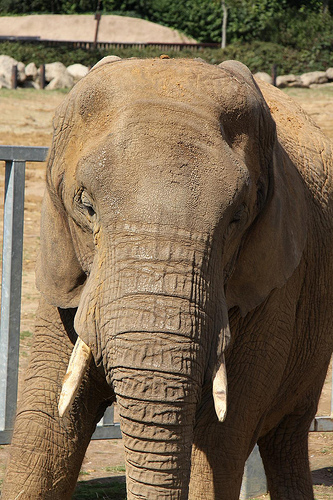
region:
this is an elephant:
[20, 38, 322, 496]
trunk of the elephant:
[80, 203, 240, 498]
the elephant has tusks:
[50, 273, 249, 449]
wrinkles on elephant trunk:
[68, 215, 240, 498]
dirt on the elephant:
[0, 31, 332, 272]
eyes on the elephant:
[71, 169, 261, 257]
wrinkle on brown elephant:
[100, 291, 209, 320]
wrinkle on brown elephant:
[108, 329, 200, 343]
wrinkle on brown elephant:
[105, 364, 196, 382]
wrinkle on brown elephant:
[115, 392, 194, 408]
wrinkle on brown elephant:
[119, 413, 192, 433]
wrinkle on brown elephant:
[118, 427, 182, 445]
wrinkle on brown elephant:
[123, 444, 179, 457]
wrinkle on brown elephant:
[124, 460, 180, 472]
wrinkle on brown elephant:
[127, 474, 182, 493]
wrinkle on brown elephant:
[14, 407, 57, 421]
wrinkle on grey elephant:
[110, 225, 216, 251]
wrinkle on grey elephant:
[104, 328, 210, 356]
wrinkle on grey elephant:
[109, 362, 199, 387]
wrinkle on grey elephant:
[115, 390, 196, 407]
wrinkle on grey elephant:
[118, 410, 192, 430]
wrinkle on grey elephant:
[120, 428, 180, 443]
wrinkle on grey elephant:
[128, 461, 182, 476]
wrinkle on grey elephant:
[14, 407, 53, 420]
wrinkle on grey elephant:
[9, 441, 46, 458]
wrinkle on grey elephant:
[126, 486, 144, 496]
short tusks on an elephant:
[56, 333, 222, 415]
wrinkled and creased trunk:
[92, 233, 215, 497]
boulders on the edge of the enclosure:
[0, 53, 332, 96]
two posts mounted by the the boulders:
[11, 62, 46, 87]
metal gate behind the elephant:
[0, 139, 118, 448]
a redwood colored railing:
[21, 37, 218, 53]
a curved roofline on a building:
[3, 11, 199, 43]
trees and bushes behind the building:
[129, 2, 332, 68]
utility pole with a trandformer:
[93, 4, 103, 46]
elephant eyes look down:
[69, 175, 251, 235]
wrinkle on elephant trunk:
[129, 489, 147, 498]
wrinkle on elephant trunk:
[128, 473, 182, 492]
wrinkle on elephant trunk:
[126, 457, 188, 473]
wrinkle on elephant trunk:
[146, 457, 171, 465]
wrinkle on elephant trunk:
[124, 444, 188, 456]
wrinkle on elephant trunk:
[119, 427, 181, 444]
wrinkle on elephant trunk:
[119, 413, 187, 429]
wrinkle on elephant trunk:
[152, 409, 183, 418]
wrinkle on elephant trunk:
[116, 391, 183, 406]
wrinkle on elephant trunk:
[108, 363, 193, 382]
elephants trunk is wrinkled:
[85, 192, 235, 494]